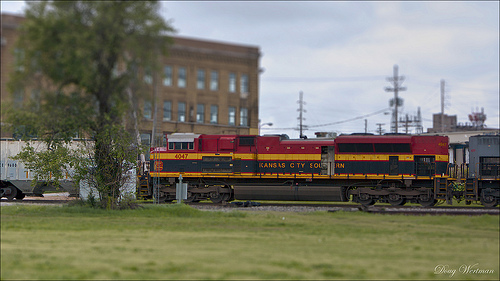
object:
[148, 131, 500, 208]
car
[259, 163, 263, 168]
letter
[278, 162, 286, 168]
letter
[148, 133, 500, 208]
train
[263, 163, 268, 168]
letter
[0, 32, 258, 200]
wall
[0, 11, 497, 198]
building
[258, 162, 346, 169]
letter